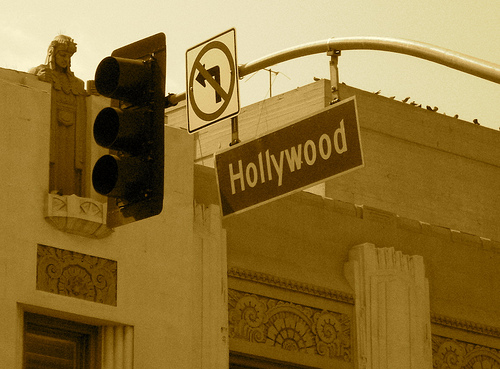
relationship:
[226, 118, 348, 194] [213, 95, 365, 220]
hollywood on sign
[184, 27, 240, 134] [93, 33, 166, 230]
no-left-turn sign fastened to traffic signal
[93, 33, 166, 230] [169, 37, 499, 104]
traffic signal attached to pole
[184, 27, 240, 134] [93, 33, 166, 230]
no-left-turn sign fastened on traffic signal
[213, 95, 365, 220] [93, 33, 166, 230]
sign fastened on traffic signal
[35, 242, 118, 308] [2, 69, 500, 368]
details are on building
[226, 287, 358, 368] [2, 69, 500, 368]
details are on building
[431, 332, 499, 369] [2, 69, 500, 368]
details are on building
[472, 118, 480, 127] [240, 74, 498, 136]
bird on top of roof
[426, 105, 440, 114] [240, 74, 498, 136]
bird on top of roof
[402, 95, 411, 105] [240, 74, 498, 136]
bird on top of roof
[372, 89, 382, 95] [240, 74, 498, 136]
bird on top of roof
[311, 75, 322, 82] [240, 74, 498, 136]
bird on top of roof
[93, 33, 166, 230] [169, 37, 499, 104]
traffic signal fastened to pole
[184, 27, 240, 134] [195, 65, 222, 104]
no-left-turn sign has arrow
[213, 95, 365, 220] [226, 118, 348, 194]
sign says hollywood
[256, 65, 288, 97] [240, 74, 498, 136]
antenna on top of roof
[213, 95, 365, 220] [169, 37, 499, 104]
sign fastened to pole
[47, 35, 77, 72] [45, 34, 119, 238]
head on top of drain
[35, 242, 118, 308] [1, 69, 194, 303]
details are on wall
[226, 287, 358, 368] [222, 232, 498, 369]
details on wall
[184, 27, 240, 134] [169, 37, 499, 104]
no-left-turn sign fastened to pole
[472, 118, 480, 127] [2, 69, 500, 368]
bird on top of building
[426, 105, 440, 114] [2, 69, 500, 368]
bird on top of building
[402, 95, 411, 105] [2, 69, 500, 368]
bird on top of building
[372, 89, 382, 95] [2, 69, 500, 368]
bird on top of building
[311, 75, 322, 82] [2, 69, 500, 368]
bird on top of building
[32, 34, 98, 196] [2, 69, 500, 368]
statue on top of building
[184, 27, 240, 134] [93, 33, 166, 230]
no-left-turn sign next to traffic signal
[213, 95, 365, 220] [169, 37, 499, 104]
sign hanging from pole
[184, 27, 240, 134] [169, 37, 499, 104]
no-left-turn sign hanging from pole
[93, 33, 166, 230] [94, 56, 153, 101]
traffic signal has light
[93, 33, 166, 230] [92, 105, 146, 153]
traffic signal has light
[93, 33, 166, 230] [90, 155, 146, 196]
traffic signal has light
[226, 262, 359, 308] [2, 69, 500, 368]
design on building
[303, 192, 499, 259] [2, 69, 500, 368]
design on building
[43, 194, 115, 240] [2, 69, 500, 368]
design on building